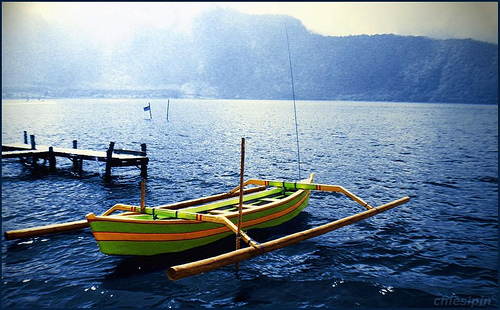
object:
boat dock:
[0, 130, 149, 188]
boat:
[85, 173, 410, 281]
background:
[1, 4, 499, 93]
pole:
[234, 139, 246, 279]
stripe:
[89, 186, 311, 256]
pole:
[160, 94, 183, 127]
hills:
[0, 2, 499, 105]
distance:
[3, 4, 496, 107]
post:
[102, 141, 116, 187]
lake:
[0, 99, 497, 310]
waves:
[442, 155, 463, 203]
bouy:
[140, 98, 153, 121]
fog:
[71, 9, 216, 79]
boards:
[195, 186, 297, 215]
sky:
[268, 7, 495, 35]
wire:
[283, 26, 302, 181]